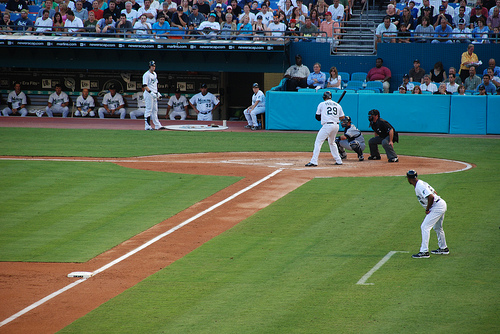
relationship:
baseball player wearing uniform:
[303, 89, 345, 169] [312, 101, 348, 163]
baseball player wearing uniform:
[408, 170, 448, 257] [414, 180, 448, 251]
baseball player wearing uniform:
[142, 59, 162, 129] [142, 71, 159, 119]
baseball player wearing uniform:
[241, 82, 265, 127] [244, 91, 264, 127]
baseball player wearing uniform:
[188, 88, 221, 122] [189, 92, 219, 119]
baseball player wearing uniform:
[169, 85, 189, 118] [167, 94, 187, 120]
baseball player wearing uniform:
[99, 84, 124, 118] [99, 93, 125, 115]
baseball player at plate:
[303, 89, 345, 169] [281, 159, 301, 166]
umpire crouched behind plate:
[362, 102, 406, 168] [276, 161, 296, 166]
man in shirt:
[458, 40, 483, 82] [454, 50, 484, 73]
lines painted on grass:
[352, 244, 413, 290] [2, 120, 495, 330]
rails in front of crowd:
[3, 21, 336, 66] [1, 2, 353, 44]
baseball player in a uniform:
[307, 92, 344, 169] [309, 100, 344, 164]